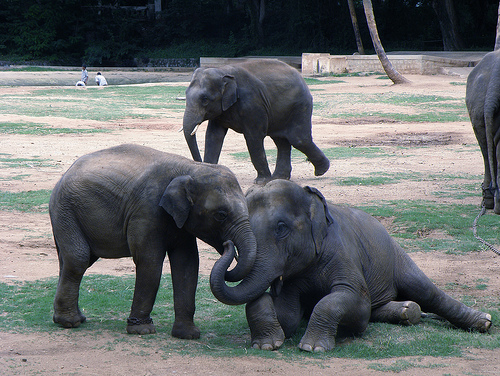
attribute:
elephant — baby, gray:
[48, 143, 258, 339]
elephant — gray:
[210, 179, 489, 352]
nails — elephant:
[254, 336, 279, 353]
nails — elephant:
[299, 334, 338, 354]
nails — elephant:
[398, 294, 423, 321]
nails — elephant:
[469, 305, 492, 330]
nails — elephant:
[126, 317, 157, 334]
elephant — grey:
[247, 180, 493, 365]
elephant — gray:
[177, 48, 335, 184]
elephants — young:
[42, 139, 492, 354]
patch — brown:
[317, 115, 474, 150]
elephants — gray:
[41, 46, 499, 354]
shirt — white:
[94, 75, 106, 85]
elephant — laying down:
[225, 175, 471, 337]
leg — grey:
[244, 289, 304, 349]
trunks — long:
[180, 115, 286, 306]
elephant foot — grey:
[469, 307, 497, 341]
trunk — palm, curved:
[361, 2, 410, 88]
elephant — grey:
[65, 151, 320, 358]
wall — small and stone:
[288, 44, 477, 84]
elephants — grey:
[166, 52, 392, 232]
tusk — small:
[191, 124, 200, 135]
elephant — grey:
[206, 164, 498, 357]